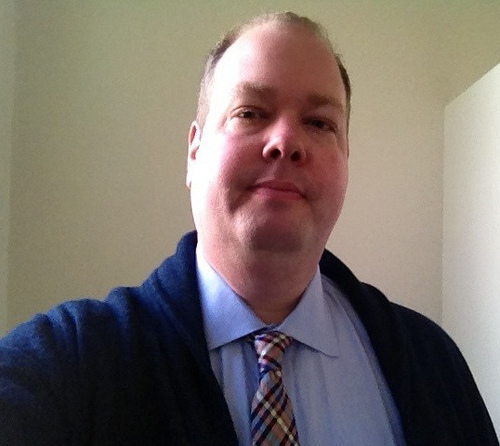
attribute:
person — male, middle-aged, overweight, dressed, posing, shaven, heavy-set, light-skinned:
[9, 7, 498, 444]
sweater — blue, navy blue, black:
[5, 225, 496, 445]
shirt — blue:
[184, 245, 403, 444]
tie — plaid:
[247, 329, 303, 444]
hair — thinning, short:
[187, 4, 367, 166]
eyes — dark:
[226, 100, 342, 135]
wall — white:
[2, 0, 497, 445]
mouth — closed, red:
[247, 175, 305, 206]